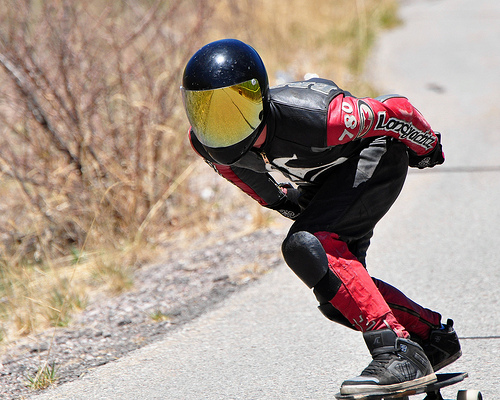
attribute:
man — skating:
[175, 47, 435, 262]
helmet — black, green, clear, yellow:
[184, 56, 270, 159]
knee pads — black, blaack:
[282, 229, 343, 289]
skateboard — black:
[348, 382, 474, 398]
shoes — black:
[373, 335, 424, 377]